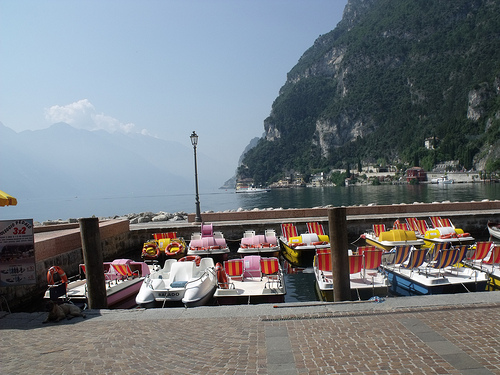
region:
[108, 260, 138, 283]
bright chair on boat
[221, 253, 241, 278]
bright chair on boat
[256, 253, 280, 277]
bright chair on boat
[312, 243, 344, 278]
bright chair on boat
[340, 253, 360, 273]
bright chair on boat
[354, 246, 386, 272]
bright chair on boat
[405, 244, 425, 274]
bright chair on boat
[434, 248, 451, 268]
bright chair on boat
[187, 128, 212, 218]
a light on a pole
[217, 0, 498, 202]
a mountain in front the ocean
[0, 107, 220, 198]
mountains on the background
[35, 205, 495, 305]
boats near a dock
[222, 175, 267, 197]
a white boat in the water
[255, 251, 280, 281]
striped chairs on a boat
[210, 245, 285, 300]
striped chairs on a boat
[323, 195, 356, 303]
a short pole on a dock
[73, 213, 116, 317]
a short pole on a dock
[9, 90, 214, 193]
a white cloud over a mountain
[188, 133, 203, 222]
a street lamp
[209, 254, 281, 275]
chairs on a boat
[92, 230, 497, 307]
many boats in a harbor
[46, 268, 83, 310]
a person standing on the ground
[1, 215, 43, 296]
a sign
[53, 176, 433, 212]
a body of water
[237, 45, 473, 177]
a mountain behind the water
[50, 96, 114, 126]
a cloud behind a mountain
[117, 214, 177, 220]
rocks in front of the water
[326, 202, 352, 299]
a post in front of the water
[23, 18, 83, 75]
white clouds in blue sky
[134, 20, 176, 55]
white clouds in blue sky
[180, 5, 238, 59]
white clouds in blue sky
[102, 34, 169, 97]
white clouds in blue sky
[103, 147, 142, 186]
white clouds in blue sky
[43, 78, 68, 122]
white clouds in blue sky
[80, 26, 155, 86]
white clouds in blue sky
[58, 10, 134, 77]
white clouds in blue sky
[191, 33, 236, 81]
white clouds in blue sky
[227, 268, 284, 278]
red and yellow seats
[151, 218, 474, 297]
boats lined up at dock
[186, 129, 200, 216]
lampost in lot for cars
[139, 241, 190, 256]
two life preserves in boat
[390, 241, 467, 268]
four striped black and gold seats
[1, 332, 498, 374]
brick on the pavement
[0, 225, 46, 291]
sign on the side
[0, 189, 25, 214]
yellow umbrella in the corner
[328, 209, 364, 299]
wooden post by the dock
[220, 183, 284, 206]
boat in the water